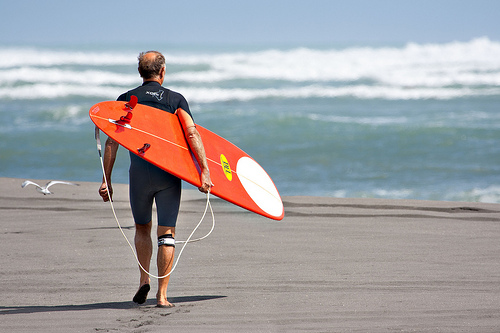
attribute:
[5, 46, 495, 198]
water — blue, white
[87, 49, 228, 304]
man — white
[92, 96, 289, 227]
board — orange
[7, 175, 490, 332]
sand — brown